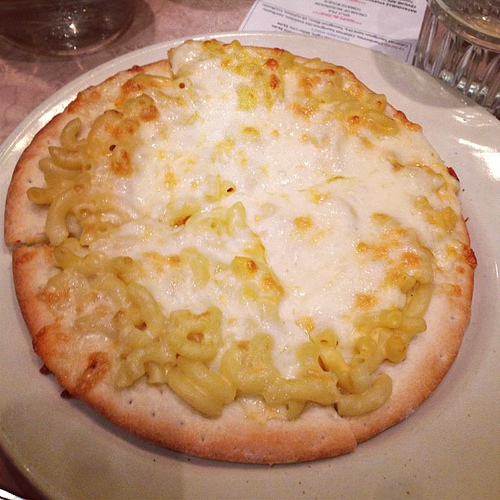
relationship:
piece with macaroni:
[0, 32, 469, 465] [147, 321, 229, 398]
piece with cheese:
[0, 32, 469, 465] [269, 187, 323, 249]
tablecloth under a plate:
[1, 9, 294, 141] [17, 25, 463, 497]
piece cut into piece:
[0, 32, 469, 465] [167, 40, 434, 192]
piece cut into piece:
[0, 32, 469, 465] [247, 162, 474, 442]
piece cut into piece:
[0, 32, 469, 465] [15, 196, 360, 462]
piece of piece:
[15, 196, 360, 462] [0, 32, 469, 465]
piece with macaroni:
[0, 32, 469, 465] [168, 358, 234, 417]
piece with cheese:
[0, 32, 469, 465] [137, 265, 220, 312]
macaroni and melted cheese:
[57, 122, 262, 378] [115, 90, 387, 349]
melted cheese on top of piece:
[115, 90, 387, 349] [0, 32, 469, 465]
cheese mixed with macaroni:
[69, 42, 450, 380] [23, 38, 458, 416]